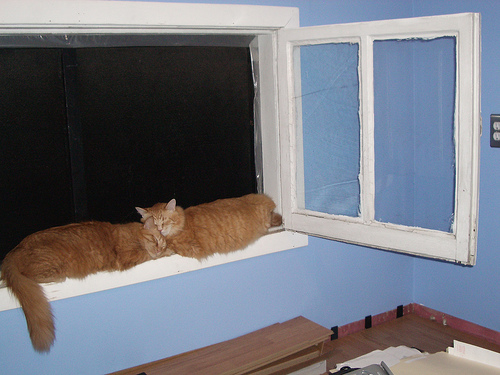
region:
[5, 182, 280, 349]
the orange cats in the window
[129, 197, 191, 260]
the cats heads snuggling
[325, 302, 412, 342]
blacktape on the baseboard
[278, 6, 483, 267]
the open windowframe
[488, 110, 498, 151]
the electrical socket on the wall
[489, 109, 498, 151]
the white plugs in the socket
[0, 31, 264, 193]
the black cover on the window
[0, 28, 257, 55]
the tape in the window seal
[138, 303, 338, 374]
the wood under the open window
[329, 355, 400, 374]
the grey piece on the floor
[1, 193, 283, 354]
two cats sleeping on a window sill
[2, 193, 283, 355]
cats sleeping on the window sill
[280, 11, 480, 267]
a wood door to the window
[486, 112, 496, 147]
a gray electrical plate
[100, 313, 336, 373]
wooden planks for the floor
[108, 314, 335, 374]
brown wooden floor material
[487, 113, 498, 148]
an electrical socket on the wall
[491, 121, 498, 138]
two white sockets on outlet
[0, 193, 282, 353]
two auburn cats on a window sill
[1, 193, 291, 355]
Cats on the window sill.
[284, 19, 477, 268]
Window on the frame.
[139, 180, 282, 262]
Orange color on the cat.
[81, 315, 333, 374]
Wood floor blanks by the window.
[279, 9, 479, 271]
White frame on the window.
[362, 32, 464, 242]
glass pane in the window.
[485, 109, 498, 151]
Electrical outlet on the wall.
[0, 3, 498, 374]
blue color on the walls.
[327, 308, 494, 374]
Hardwood flooring on the ground.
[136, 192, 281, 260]
yellow cat sleeping in window sill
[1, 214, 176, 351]
window cat sleeping in window sill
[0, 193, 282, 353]
two yellow cats sleeping in window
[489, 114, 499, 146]
electric outlet on wall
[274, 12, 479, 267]
window with white frame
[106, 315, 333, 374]
flooring panels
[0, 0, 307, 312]
white frame around window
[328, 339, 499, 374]
box sitting on floor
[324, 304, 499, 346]
red strip at bottom of wall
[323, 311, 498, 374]
wood flooring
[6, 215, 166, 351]
cat on the window sill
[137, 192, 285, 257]
cat on the window sill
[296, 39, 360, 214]
glass window in the pane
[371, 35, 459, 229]
glass in the pane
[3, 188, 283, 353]
cats on the sill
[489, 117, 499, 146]
outlet on the wall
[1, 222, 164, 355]
cat sleeping on the sill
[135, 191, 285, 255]
cat sleeping on the sill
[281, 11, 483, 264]
window is open in the room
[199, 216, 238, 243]
the fur is orange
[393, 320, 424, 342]
a wooden floor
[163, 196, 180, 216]
the cats ear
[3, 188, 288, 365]
a pair of cats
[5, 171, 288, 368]
the cats are laying down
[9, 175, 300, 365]
the cats are sleeping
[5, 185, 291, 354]
cats on a window seal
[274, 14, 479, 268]
white trim on window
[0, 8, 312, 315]
the window frame is white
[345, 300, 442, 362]
the floor is brown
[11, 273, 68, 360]
tail of the cat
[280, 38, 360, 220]
pane on the window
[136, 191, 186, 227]
ears on the cat